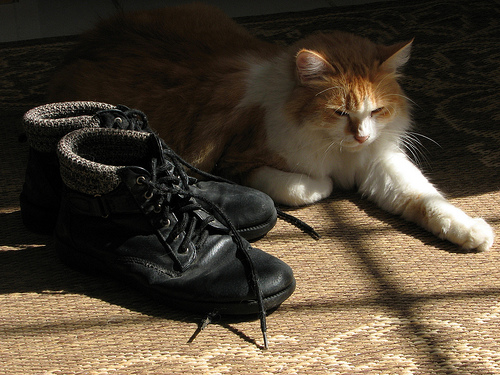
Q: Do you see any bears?
A: No, there are no bears.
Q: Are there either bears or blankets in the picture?
A: No, there are no bears or blankets.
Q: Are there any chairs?
A: No, there are no chairs.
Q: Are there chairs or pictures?
A: No, there are no chairs or pictures.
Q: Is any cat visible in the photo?
A: Yes, there is a cat.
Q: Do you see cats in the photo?
A: Yes, there is a cat.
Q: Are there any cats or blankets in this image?
A: Yes, there is a cat.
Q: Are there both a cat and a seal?
A: No, there is a cat but no seals.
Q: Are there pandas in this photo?
A: No, there are no pandas.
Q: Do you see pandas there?
A: No, there are no pandas.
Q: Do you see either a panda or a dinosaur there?
A: No, there are no pandas or dinosaurs.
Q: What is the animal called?
A: The animal is a cat.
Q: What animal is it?
A: The animal is a cat.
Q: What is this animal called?
A: This is a cat.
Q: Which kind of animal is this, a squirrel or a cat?
A: This is a cat.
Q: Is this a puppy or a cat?
A: This is a cat.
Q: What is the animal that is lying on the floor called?
A: The animal is a cat.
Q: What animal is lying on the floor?
A: The animal is a cat.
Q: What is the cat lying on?
A: The cat is lying on the floor.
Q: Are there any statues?
A: No, there are no statues.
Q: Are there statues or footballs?
A: No, there are no statues or footballs.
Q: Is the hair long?
A: Yes, the hair is long.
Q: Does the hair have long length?
A: Yes, the hair is long.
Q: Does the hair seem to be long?
A: Yes, the hair is long.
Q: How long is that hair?
A: The hair is long.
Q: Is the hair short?
A: No, the hair is long.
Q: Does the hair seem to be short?
A: No, the hair is long.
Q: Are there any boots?
A: Yes, there are boots.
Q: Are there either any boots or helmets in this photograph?
A: Yes, there are boots.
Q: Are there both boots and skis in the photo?
A: No, there are boots but no skis.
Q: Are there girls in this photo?
A: No, there are no girls.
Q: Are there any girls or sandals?
A: No, there are no girls or sandals.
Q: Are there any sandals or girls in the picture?
A: No, there are no girls or sandals.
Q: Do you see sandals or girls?
A: No, there are no girls or sandals.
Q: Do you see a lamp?
A: No, there are no lamps.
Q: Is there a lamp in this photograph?
A: No, there are no lamps.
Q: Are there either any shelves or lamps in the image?
A: No, there are no lamps or shelves.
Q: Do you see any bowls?
A: No, there are no bowls.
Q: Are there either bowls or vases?
A: No, there are no bowls or vases.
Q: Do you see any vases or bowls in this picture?
A: No, there are no bowls or vases.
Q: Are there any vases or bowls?
A: No, there are no bowls or vases.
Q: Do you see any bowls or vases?
A: No, there are no bowls or vases.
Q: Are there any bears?
A: No, there are no bears.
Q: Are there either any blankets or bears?
A: No, there are no bears or blankets.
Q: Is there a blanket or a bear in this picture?
A: No, there are no bears or blankets.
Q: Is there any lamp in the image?
A: No, there are no lamps.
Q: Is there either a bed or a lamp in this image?
A: No, there are no lamps or beds.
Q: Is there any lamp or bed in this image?
A: No, there are no lamps or beds.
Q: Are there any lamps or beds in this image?
A: No, there are no lamps or beds.